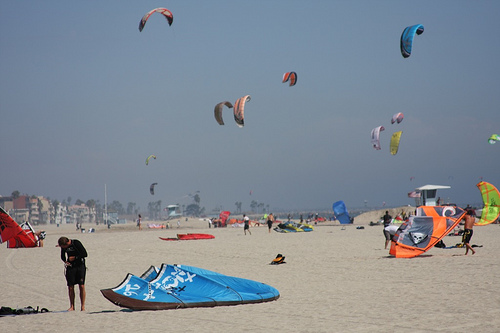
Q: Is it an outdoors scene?
A: Yes, it is outdoors.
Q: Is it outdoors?
A: Yes, it is outdoors.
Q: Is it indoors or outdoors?
A: It is outdoors.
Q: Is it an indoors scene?
A: No, it is outdoors.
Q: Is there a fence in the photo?
A: No, there are no fences.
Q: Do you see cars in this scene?
A: No, there are no cars.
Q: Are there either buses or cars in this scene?
A: No, there are no cars or buses.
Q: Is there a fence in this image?
A: No, there are no fences.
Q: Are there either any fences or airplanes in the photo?
A: No, there are no fences or airplanes.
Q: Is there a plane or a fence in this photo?
A: No, there are no fences or airplanes.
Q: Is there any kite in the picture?
A: Yes, there is a kite.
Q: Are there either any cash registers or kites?
A: Yes, there is a kite.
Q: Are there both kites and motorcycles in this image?
A: No, there is a kite but no motorcycles.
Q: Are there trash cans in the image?
A: No, there are no trash cans.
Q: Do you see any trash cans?
A: No, there are no trash cans.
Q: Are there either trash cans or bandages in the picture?
A: No, there are no trash cans or bandages.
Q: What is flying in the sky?
A: The kite is flying in the sky.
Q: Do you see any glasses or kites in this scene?
A: Yes, there is a kite.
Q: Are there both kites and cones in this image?
A: No, there is a kite but no cones.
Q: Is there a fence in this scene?
A: No, there are no fences.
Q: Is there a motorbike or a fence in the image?
A: No, there are no fences or motorcycles.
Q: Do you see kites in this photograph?
A: Yes, there is a kite.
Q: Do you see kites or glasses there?
A: Yes, there is a kite.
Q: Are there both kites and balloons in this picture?
A: No, there is a kite but no balloons.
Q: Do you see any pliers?
A: No, there are no pliers.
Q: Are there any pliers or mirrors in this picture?
A: No, there are no pliers or mirrors.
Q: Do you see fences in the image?
A: No, there are no fences.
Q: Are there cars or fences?
A: No, there are no fences or cars.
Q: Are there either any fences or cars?
A: No, there are no fences or cars.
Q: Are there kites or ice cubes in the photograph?
A: Yes, there is a kite.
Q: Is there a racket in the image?
A: No, there are no rackets.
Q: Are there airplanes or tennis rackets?
A: No, there are no tennis rackets or airplanes.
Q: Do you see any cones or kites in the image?
A: Yes, there is a kite.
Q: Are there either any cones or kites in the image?
A: Yes, there is a kite.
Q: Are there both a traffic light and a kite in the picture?
A: No, there is a kite but no traffic lights.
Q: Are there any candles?
A: No, there are no candles.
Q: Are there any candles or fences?
A: No, there are no candles or fences.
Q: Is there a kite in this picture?
A: Yes, there is a kite.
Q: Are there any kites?
A: Yes, there is a kite.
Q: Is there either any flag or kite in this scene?
A: Yes, there is a kite.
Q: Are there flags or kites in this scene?
A: Yes, there is a kite.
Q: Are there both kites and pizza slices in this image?
A: No, there is a kite but no pizza slices.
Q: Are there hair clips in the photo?
A: No, there are no hair clips.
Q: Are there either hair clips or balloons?
A: No, there are no hair clips or balloons.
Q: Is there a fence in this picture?
A: No, there are no fences.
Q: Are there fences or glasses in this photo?
A: No, there are no fences or glasses.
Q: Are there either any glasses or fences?
A: No, there are no glasses or fences.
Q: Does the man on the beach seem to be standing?
A: Yes, the man is standing.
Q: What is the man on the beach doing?
A: The man is standing.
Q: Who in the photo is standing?
A: The man is standing.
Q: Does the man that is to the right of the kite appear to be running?
A: No, the man is standing.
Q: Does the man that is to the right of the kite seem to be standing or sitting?
A: The man is standing.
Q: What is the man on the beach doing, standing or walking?
A: The man is standing.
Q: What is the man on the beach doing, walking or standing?
A: The man is standing.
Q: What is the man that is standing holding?
A: The man is holding the kite.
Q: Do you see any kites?
A: Yes, there is a kite.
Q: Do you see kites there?
A: Yes, there is a kite.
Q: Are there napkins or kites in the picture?
A: Yes, there is a kite.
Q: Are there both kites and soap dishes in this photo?
A: No, there is a kite but no soap dishes.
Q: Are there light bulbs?
A: No, there are no light bulbs.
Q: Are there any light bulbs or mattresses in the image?
A: No, there are no light bulbs or mattresses.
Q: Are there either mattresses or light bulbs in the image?
A: No, there are no light bulbs or mattresses.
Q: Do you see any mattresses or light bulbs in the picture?
A: No, there are no light bulbs or mattresses.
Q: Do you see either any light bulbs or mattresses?
A: No, there are no light bulbs or mattresses.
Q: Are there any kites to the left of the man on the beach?
A: Yes, there is a kite to the left of the man.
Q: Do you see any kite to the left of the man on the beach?
A: Yes, there is a kite to the left of the man.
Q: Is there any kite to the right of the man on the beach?
A: No, the kite is to the left of the man.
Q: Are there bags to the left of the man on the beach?
A: No, there is a kite to the left of the man.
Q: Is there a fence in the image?
A: No, there are no fences.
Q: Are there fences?
A: No, there are no fences.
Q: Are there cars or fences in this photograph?
A: No, there are no fences or cars.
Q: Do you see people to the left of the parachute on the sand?
A: Yes, there is a person to the left of the parachute.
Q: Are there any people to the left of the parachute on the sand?
A: Yes, there is a person to the left of the parachute.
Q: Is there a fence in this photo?
A: No, there are no fences.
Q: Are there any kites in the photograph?
A: Yes, there is a kite.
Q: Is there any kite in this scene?
A: Yes, there is a kite.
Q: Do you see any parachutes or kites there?
A: Yes, there is a kite.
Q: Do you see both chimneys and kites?
A: No, there is a kite but no chimneys.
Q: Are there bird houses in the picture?
A: No, there are no bird houses.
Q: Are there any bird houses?
A: No, there are no bird houses.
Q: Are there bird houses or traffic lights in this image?
A: No, there are no bird houses or traffic lights.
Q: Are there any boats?
A: No, there are no boats.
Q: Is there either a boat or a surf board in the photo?
A: No, there are no boats or surfboards.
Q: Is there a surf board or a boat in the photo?
A: No, there are no boats or surfboards.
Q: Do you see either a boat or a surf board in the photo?
A: No, there are no boats or surfboards.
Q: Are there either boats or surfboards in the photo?
A: No, there are no boats or surfboards.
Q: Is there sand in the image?
A: Yes, there is sand.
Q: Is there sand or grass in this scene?
A: Yes, there is sand.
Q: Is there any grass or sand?
A: Yes, there is sand.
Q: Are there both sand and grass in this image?
A: No, there is sand but no grass.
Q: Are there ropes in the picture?
A: No, there are no ropes.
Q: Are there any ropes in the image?
A: No, there are no ropes.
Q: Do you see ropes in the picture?
A: No, there are no ropes.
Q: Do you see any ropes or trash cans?
A: No, there are no ropes or trash cans.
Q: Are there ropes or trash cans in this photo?
A: No, there are no ropes or trash cans.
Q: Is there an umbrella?
A: No, there are no umbrellas.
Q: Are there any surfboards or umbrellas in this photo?
A: No, there are no umbrellas or surfboards.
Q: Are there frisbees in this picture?
A: No, there are no frisbees.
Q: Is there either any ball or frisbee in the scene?
A: No, there are no frisbees or balls.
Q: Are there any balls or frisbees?
A: No, there are no frisbees or balls.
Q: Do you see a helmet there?
A: No, there are no helmets.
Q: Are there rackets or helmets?
A: No, there are no helmets or rackets.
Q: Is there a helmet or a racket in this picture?
A: No, there are no helmets or rackets.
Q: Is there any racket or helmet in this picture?
A: No, there are no helmets or rackets.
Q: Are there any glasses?
A: No, there are no glasses.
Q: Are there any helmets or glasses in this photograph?
A: No, there are no glasses or helmets.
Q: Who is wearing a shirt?
A: The man is wearing a shirt.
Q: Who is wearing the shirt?
A: The man is wearing a shirt.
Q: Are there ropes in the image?
A: No, there are no ropes.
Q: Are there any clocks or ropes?
A: No, there are no ropes or clocks.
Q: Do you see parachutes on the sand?
A: Yes, there is a parachute on the sand.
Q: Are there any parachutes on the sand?
A: Yes, there is a parachute on the sand.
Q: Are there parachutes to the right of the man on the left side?
A: Yes, there is a parachute to the right of the man.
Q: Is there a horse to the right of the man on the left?
A: No, there is a parachute to the right of the man.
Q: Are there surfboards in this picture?
A: No, there are no surfboards.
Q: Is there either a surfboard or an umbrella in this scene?
A: No, there are no surfboards or umbrellas.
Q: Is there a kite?
A: Yes, there is a kite.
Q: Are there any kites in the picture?
A: Yes, there is a kite.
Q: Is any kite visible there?
A: Yes, there is a kite.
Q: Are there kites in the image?
A: Yes, there is a kite.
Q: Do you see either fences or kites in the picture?
A: Yes, there is a kite.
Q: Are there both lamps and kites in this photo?
A: No, there is a kite but no lamps.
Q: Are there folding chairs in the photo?
A: No, there are no folding chairs.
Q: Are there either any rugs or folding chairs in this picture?
A: No, there are no folding chairs or rugs.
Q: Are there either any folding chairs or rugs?
A: No, there are no folding chairs or rugs.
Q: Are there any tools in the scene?
A: No, there are no tools.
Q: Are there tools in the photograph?
A: No, there are no tools.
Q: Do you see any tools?
A: No, there are no tools.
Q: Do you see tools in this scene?
A: No, there are no tools.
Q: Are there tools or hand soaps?
A: No, there are no tools or hand soaps.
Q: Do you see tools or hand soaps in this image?
A: No, there are no tools or hand soaps.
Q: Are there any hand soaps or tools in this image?
A: No, there are no tools or hand soaps.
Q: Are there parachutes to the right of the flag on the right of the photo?
A: Yes, there is a parachute to the right of the flag.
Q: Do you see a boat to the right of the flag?
A: No, there is a parachute to the right of the flag.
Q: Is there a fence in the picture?
A: No, there are no fences.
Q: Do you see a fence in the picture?
A: No, there are no fences.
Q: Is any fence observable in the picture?
A: No, there are no fences.